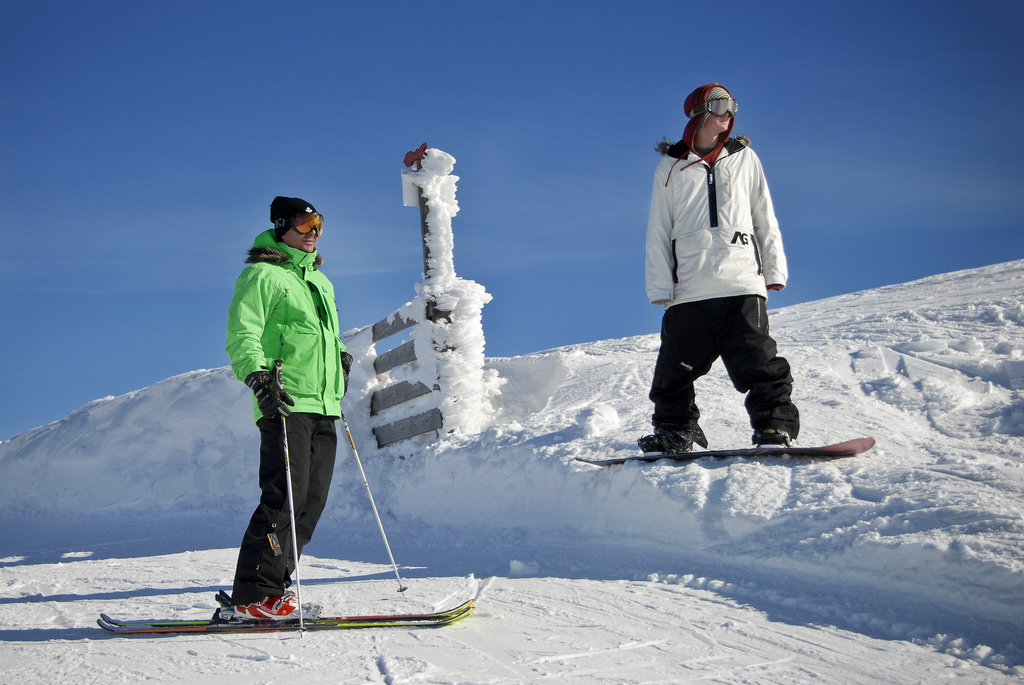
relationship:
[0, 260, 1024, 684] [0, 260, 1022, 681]
ground on ground